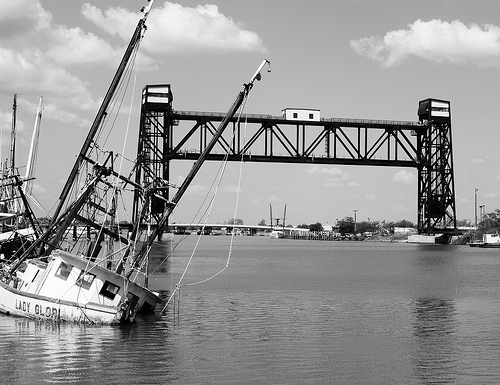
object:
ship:
[0, 0, 165, 336]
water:
[0, 231, 495, 385]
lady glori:
[14, 299, 62, 321]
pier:
[125, 220, 317, 236]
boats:
[173, 230, 191, 236]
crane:
[269, 203, 288, 239]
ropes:
[175, 87, 252, 288]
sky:
[0, 0, 500, 228]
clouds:
[346, 9, 500, 73]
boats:
[0, 246, 163, 329]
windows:
[53, 261, 75, 283]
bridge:
[128, 220, 313, 236]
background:
[0, 82, 499, 248]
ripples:
[29, 346, 174, 357]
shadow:
[3, 322, 177, 385]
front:
[20, 256, 165, 327]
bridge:
[129, 83, 460, 243]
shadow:
[412, 298, 457, 382]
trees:
[336, 216, 356, 236]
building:
[281, 107, 322, 122]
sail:
[21, 96, 46, 214]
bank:
[375, 219, 499, 250]